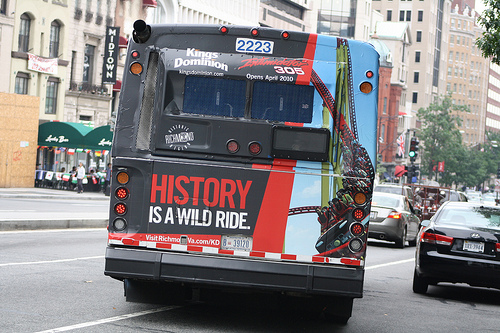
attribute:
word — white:
[159, 203, 176, 229]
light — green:
[399, 128, 424, 175]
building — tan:
[441, 12, 488, 171]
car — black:
[414, 196, 497, 298]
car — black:
[412, 198, 499, 311]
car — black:
[412, 200, 498, 294]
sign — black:
[61, 13, 150, 93]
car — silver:
[371, 189, 427, 251]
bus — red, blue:
[109, 15, 379, 325]